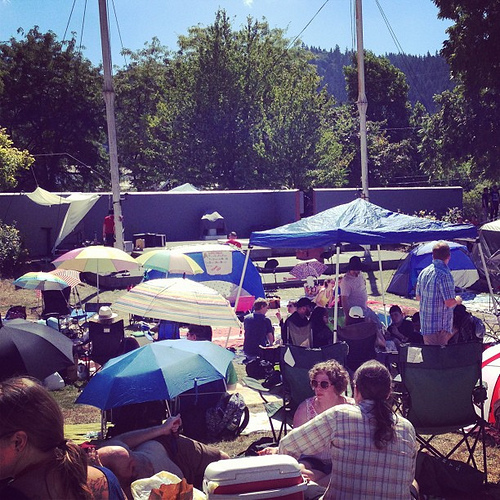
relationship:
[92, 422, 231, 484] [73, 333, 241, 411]
person holding umbrella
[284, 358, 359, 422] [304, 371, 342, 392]
woman wearing sunglasses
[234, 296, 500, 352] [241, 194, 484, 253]
people sitting under canopy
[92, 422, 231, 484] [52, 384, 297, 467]
person in grass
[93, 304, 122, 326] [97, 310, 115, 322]
hat has a stripe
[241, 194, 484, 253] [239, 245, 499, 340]
canopy has poles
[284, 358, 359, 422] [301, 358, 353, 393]
woman has hair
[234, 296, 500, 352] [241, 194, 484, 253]
people are under canopy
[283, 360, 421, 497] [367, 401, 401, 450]
man has ponytail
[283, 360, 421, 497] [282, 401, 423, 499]
man wearing a shirt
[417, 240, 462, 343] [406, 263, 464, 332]
man wearing a shirt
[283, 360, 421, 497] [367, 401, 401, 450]
man has a ponytail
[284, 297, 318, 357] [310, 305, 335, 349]
person next to person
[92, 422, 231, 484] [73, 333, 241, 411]
person holding an umbrella